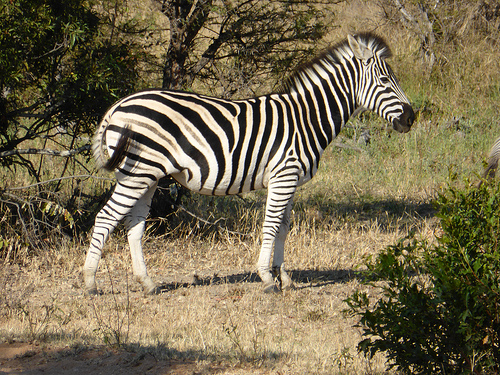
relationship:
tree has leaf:
[0, 1, 140, 235] [109, 91, 122, 101]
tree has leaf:
[0, 1, 140, 235] [70, 33, 78, 51]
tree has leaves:
[0, 1, 140, 235] [1, 1, 136, 101]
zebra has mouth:
[82, 30, 416, 298] [394, 101, 416, 134]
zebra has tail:
[82, 30, 416, 298] [92, 107, 133, 171]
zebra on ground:
[82, 30, 416, 298] [4, 189, 443, 373]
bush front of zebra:
[347, 183, 498, 374] [82, 30, 416, 298]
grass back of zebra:
[317, 88, 499, 199] [82, 30, 416, 298]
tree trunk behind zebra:
[149, 1, 213, 236] [82, 30, 416, 298]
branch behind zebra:
[189, 0, 318, 92] [82, 30, 416, 298]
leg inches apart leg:
[77, 172, 140, 297] [127, 189, 162, 296]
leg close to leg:
[259, 177, 295, 284] [274, 215, 295, 288]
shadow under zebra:
[156, 266, 427, 292] [82, 30, 416, 298]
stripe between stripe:
[118, 106, 189, 149] [109, 119, 178, 150]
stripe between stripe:
[118, 106, 189, 149] [120, 105, 184, 143]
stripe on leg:
[270, 197, 291, 204] [259, 177, 295, 284]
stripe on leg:
[271, 179, 298, 185] [259, 177, 295, 284]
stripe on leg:
[264, 217, 282, 226] [259, 177, 295, 284]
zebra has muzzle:
[82, 30, 416, 298] [394, 101, 416, 134]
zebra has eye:
[82, 30, 416, 298] [378, 74, 390, 85]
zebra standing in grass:
[82, 30, 416, 298] [4, 189, 443, 373]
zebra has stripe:
[82, 30, 416, 298] [109, 119, 178, 150]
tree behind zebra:
[141, 4, 327, 241] [82, 30, 416, 298]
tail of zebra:
[92, 107, 133, 171] [82, 30, 416, 298]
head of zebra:
[357, 30, 415, 135] [82, 30, 416, 298]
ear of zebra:
[345, 32, 374, 61] [82, 30, 416, 298]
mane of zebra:
[277, 32, 393, 91] [82, 30, 416, 298]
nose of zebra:
[400, 102, 419, 125] [82, 30, 416, 298]